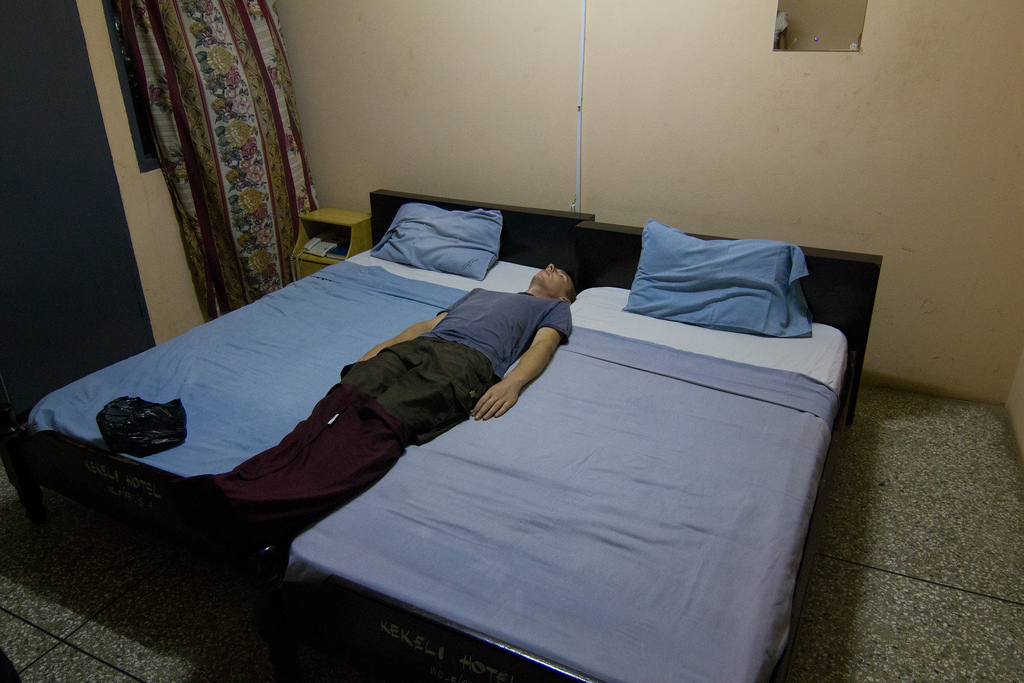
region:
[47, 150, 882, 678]
Man lying in the middle of two twin beds.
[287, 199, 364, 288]
A small yellow nightstand.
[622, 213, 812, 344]
Pillow with a blue pillowcase.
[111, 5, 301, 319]
Long curtain in front of window frame.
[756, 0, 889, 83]
Cubby hole in the wall.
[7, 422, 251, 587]
Name of bed on the footboard.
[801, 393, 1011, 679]
Speckled, tiled flooring.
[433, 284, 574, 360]
Blue t-shirt with short sleeves.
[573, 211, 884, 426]
Rectangular dark headboard on bed.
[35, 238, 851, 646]
Blue and white sheets on bed.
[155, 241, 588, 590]
person laying on bed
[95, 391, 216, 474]
a black bag on bed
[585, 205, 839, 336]
a blue pillow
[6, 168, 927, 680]
two beds pushed together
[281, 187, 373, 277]
a yellow nightstand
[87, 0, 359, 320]
a curtain on a window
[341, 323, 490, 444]
pants are green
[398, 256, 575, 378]
the man's shirt is grey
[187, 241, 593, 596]
man laying between two beds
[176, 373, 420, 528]
a blanket on man's legs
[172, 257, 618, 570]
A man lying down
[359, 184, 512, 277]
The blue pillow to the left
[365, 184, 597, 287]
The headboard to the left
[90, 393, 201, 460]
The black bag on the bed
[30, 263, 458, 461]
The blue sheet on the left bed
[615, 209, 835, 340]
The blue pillow on the right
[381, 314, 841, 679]
The blue sheet on the right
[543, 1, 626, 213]
The white pipe on the wall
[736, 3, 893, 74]
The square hole in the wall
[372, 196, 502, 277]
pillow with blue case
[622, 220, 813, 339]
pillow with blue case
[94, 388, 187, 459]
black plastic bag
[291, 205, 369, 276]
yellow colored night stand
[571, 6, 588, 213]
small white stripe on the wall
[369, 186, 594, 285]
black head board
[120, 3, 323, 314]
curtain with a floral pattern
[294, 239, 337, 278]
white corded telephone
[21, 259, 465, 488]
light blue comforter on a bed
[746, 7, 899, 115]
a mirror on the bed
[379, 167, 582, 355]
a pillow is blue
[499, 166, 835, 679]
a mattress on the bed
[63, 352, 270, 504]
a bag on the bed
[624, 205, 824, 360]
a blue pillow on the bed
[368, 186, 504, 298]
a blue pillow on a bed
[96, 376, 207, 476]
a small black bag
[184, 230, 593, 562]
a man lying between beds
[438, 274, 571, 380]
the shirt is blue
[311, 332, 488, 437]
the shorts are brown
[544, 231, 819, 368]
a blue pillow on a bed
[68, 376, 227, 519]
a black bag on the bed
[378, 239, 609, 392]
a man on the bed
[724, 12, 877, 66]
a marrow on the wall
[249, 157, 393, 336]
a brown table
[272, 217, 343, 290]
a white phone on the table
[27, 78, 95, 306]
a dark gray door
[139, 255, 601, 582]
a man with blue and gray on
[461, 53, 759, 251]
a wall panted pink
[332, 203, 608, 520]
A man laying between two beds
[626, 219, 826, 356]
A blue pillow on the bed.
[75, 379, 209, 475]
A black plastic bag on the bed.